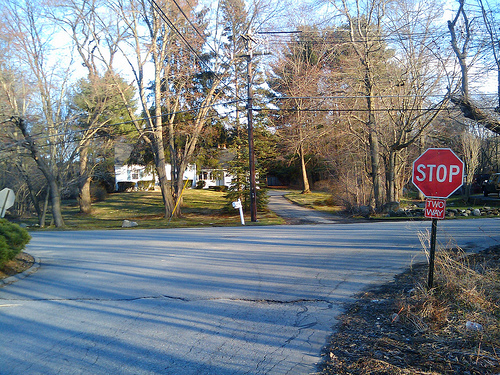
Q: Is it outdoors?
A: Yes, it is outdoors.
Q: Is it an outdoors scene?
A: Yes, it is outdoors.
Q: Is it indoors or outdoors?
A: It is outdoors.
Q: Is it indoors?
A: No, it is outdoors.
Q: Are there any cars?
A: No, there are no cars.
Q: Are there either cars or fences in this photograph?
A: No, there are no cars or fences.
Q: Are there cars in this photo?
A: No, there are no cars.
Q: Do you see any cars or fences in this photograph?
A: No, there are no cars or fences.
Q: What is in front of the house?
A: The tree is in front of the house.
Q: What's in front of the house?
A: The tree is in front of the house.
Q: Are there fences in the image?
A: No, there are no fences.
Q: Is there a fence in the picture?
A: No, there are no fences.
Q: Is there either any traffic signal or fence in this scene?
A: No, there are no fences or traffic lights.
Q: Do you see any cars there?
A: No, there are no cars.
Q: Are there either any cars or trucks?
A: No, there are no cars or trucks.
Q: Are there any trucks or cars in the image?
A: No, there are no cars or trucks.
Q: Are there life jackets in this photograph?
A: No, there are no life jackets.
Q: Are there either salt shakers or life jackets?
A: No, there are no life jackets or salt shakers.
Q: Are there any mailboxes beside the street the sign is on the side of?
A: Yes, there is a mailbox beside the street.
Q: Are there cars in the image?
A: No, there are no cars.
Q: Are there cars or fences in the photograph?
A: No, there are no cars or fences.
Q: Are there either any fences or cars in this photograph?
A: No, there are no cars or fences.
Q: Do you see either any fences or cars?
A: No, there are no cars or fences.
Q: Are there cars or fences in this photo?
A: No, there are no cars or fences.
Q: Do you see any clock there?
A: No, there are no clocks.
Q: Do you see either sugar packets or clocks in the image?
A: No, there are no clocks or sugar packets.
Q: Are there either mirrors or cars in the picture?
A: No, there are no cars or mirrors.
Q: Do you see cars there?
A: No, there are no cars.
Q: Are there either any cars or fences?
A: No, there are no cars or fences.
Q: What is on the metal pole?
A: The sign is on the pole.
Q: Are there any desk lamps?
A: No, there are no desk lamps.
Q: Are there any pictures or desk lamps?
A: No, there are no desk lamps or pictures.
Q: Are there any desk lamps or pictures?
A: No, there are no desk lamps or pictures.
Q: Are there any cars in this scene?
A: No, there are no cars.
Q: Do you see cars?
A: No, there are no cars.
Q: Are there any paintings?
A: No, there are no paintings.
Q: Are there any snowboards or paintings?
A: No, there are no paintings or snowboards.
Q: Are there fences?
A: No, there are no fences.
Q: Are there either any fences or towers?
A: No, there are no fences or towers.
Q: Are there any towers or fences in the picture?
A: No, there are no fences or towers.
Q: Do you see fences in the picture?
A: No, there are no fences.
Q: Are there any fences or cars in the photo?
A: No, there are no fences or cars.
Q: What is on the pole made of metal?
A: The sign is on the pole.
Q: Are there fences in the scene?
A: No, there are no fences.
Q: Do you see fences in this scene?
A: No, there are no fences.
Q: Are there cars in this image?
A: No, there are no cars.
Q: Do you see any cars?
A: No, there are no cars.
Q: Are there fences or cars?
A: No, there are no cars or fences.